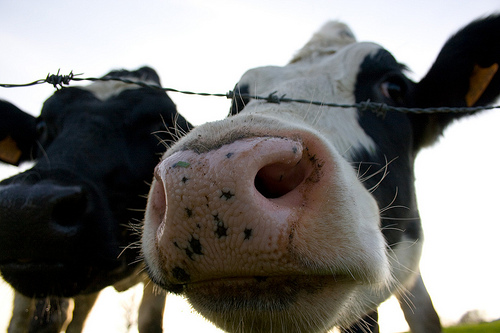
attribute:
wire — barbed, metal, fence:
[2, 62, 497, 134]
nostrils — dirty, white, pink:
[146, 130, 326, 256]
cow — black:
[136, 1, 493, 330]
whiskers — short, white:
[344, 151, 408, 224]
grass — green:
[426, 320, 499, 331]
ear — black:
[411, 13, 499, 147]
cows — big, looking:
[1, 10, 480, 329]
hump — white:
[278, 16, 362, 65]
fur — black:
[374, 133, 413, 207]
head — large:
[135, 15, 499, 333]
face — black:
[141, 72, 408, 333]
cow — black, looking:
[1, 60, 187, 306]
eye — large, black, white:
[378, 70, 410, 114]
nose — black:
[2, 181, 92, 265]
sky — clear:
[2, 2, 490, 110]